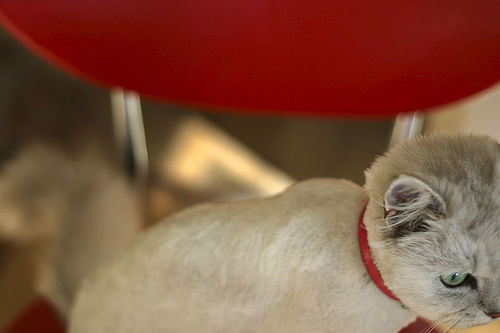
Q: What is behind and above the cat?
A: A semi circular portion of a red table.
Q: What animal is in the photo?
A: Cat.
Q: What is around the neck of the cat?
A: Collar.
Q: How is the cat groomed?
A: Short hair cut.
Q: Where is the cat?
A: On a chair.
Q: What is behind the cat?
A: The back of the chair.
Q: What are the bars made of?
A: Metal.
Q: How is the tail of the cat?
A: Bushy.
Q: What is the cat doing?
A: Sitting.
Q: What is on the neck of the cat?
A: Collar.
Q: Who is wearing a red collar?
A: Cat.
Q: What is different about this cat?
A: Red collar on.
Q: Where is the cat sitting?
A: Chair.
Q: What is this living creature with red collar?
A: Cat.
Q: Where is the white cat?
A: Red chair.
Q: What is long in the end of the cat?
A: Tail.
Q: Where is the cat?
A: Chair.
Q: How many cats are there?
A: One.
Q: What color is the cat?
A: Grey.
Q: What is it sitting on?
A: The chair.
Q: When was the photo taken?
A: During the day.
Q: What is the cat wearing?
A: A collar.